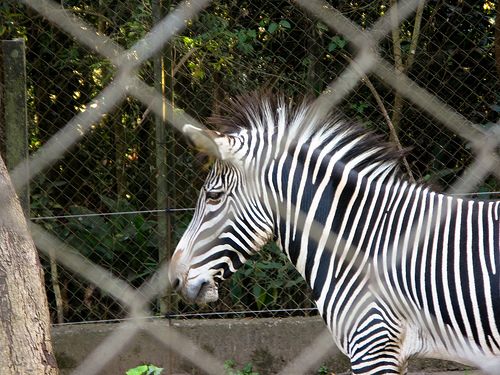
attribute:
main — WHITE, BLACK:
[201, 81, 417, 182]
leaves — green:
[97, 20, 273, 95]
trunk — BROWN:
[3, 155, 59, 369]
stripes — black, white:
[277, 160, 372, 237]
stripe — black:
[482, 202, 498, 334]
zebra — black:
[159, 86, 498, 373]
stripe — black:
[191, 246, 243, 266]